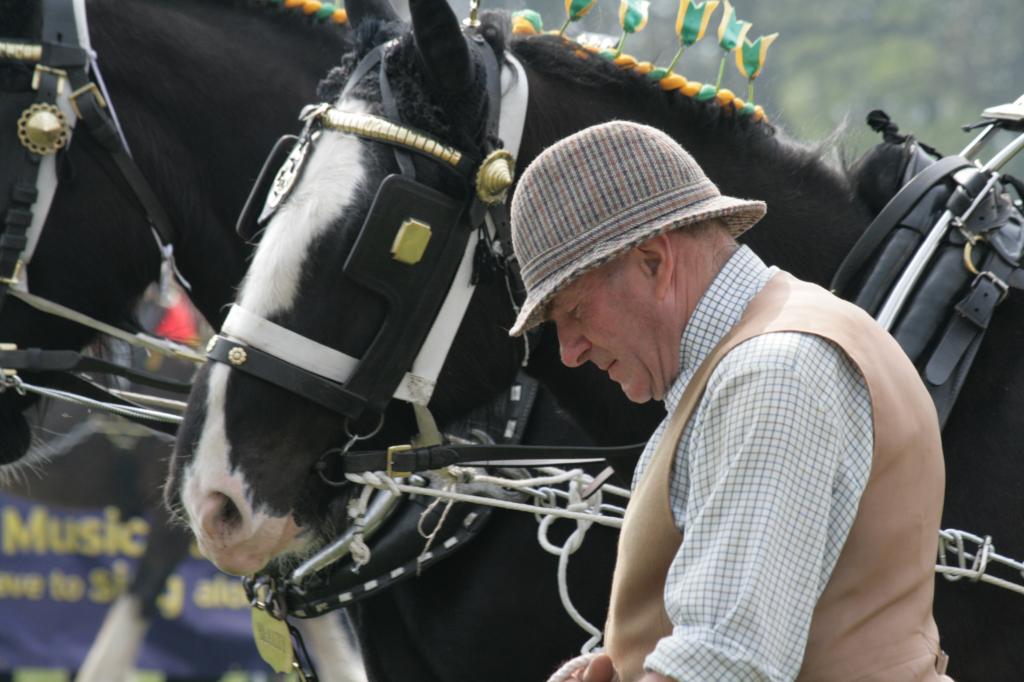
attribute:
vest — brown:
[855, 390, 944, 650]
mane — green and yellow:
[575, 107, 736, 136]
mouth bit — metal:
[253, 392, 435, 663]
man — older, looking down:
[482, 90, 966, 678]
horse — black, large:
[162, 15, 1014, 674]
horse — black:
[9, 23, 347, 462]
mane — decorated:
[508, 23, 790, 142]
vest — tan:
[594, 268, 970, 677]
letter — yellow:
[2, 492, 54, 566]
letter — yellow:
[73, 507, 113, 574]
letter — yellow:
[95, 507, 154, 555]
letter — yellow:
[39, 507, 87, 570]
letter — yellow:
[69, 507, 102, 555]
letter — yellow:
[39, 510, 76, 550]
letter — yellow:
[117, 514, 143, 554]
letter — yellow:
[73, 507, 99, 551]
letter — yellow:
[95, 496, 124, 555]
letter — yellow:
[43, 510, 80, 565]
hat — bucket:
[478, 101, 779, 350]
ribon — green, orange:
[519, 15, 764, 115]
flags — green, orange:
[553, 0, 776, 98]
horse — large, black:
[1, 0, 628, 673]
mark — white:
[192, 82, 376, 450]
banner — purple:
[1, 397, 276, 676]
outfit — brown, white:
[501, 116, 966, 680]